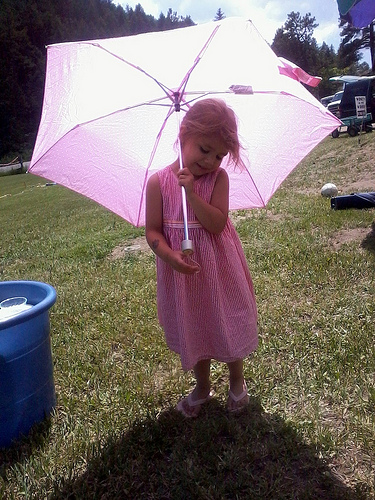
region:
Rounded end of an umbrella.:
[180, 240, 196, 255]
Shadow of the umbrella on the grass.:
[47, 391, 373, 498]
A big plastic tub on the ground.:
[0, 281, 57, 454]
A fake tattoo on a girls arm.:
[150, 238, 160, 251]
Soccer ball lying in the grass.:
[320, 183, 337, 199]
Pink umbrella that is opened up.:
[25, 13, 344, 225]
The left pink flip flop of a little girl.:
[221, 376, 247, 412]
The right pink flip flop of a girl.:
[175, 388, 208, 419]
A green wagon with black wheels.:
[331, 111, 373, 137]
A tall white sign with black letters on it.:
[354, 94, 368, 118]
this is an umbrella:
[72, 32, 129, 163]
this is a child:
[154, 101, 248, 420]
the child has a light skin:
[202, 207, 214, 219]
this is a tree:
[286, 13, 314, 51]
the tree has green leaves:
[296, 11, 309, 31]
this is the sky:
[261, 3, 274, 18]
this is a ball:
[322, 181, 335, 195]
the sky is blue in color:
[196, 4, 204, 9]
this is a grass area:
[68, 284, 119, 353]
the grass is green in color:
[94, 393, 118, 422]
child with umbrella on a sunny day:
[30, 0, 341, 310]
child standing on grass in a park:
[21, 25, 355, 425]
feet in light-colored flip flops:
[147, 364, 269, 427]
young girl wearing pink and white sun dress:
[136, 156, 266, 378]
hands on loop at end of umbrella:
[161, 233, 212, 278]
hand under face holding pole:
[157, 94, 241, 203]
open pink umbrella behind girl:
[30, 22, 331, 232]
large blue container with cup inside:
[0, 266, 67, 458]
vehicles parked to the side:
[320, 27, 369, 139]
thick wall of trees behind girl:
[7, 8, 194, 176]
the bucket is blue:
[2, 282, 75, 447]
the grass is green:
[89, 376, 327, 467]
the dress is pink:
[159, 286, 269, 367]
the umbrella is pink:
[49, 65, 340, 206]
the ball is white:
[312, 177, 344, 205]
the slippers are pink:
[159, 386, 261, 413]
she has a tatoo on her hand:
[147, 240, 171, 256]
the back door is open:
[334, 75, 370, 124]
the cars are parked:
[317, 94, 340, 115]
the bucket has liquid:
[9, 285, 63, 433]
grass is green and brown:
[167, 369, 301, 475]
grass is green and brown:
[88, 328, 320, 496]